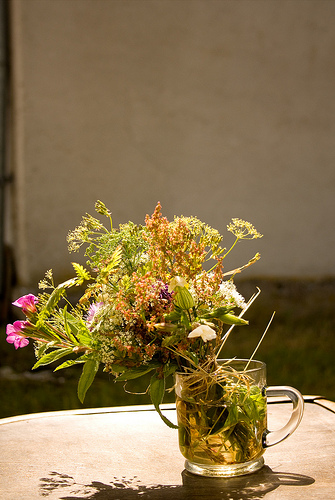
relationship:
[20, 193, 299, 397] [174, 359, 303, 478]
flowers in cup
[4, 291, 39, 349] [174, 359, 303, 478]
purple flower in cup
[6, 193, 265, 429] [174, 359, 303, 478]
flowers in cup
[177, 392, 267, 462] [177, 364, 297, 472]
water in glass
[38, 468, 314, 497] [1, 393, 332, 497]
shadow on table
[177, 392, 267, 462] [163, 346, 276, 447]
water in glass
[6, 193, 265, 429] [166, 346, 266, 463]
flowers has stems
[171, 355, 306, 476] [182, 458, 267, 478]
cup has base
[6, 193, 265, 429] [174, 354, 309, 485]
flowers are on mug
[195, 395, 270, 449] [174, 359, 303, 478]
stem on cup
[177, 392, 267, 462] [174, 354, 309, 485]
water on mug